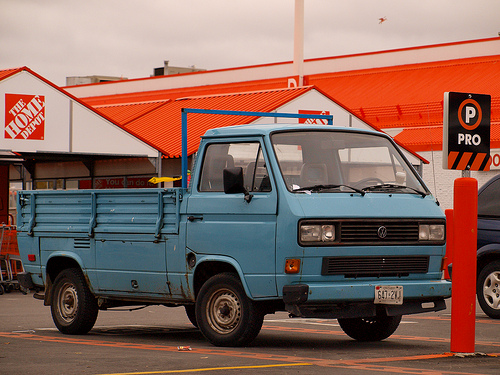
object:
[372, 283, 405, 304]
license plate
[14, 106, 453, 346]
truck